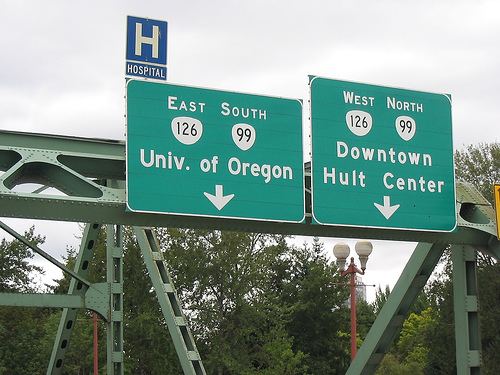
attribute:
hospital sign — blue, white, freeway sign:
[123, 11, 171, 84]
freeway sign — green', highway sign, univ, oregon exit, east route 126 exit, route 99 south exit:
[124, 75, 306, 225]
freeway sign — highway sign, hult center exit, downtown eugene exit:
[306, 65, 455, 234]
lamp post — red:
[325, 238, 382, 364]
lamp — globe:
[326, 240, 352, 275]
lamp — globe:
[354, 241, 376, 272]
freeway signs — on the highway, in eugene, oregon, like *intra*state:
[115, 69, 461, 242]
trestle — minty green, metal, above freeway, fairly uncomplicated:
[2, 122, 499, 375]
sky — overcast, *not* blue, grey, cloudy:
[2, 2, 499, 345]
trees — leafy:
[2, 134, 499, 375]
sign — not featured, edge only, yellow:
[487, 179, 499, 245]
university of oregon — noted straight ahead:
[135, 145, 295, 185]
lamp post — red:
[76, 303, 106, 374]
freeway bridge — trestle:
[0, 125, 499, 371]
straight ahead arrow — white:
[197, 180, 241, 213]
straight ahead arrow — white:
[368, 191, 407, 222]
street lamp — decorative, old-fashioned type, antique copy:
[320, 241, 385, 366]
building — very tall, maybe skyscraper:
[342, 271, 370, 312]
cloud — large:
[268, 233, 423, 277]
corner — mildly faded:
[451, 177, 498, 249]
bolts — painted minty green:
[0, 145, 126, 213]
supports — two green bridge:
[4, 219, 484, 365]